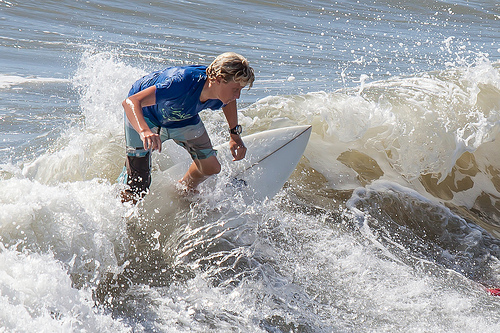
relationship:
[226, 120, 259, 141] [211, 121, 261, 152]
watch on wrist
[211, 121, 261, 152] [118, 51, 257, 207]
wrist of man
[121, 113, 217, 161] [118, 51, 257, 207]
shortsa of man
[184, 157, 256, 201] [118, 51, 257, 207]
knee of man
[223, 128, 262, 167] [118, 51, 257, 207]
hand or man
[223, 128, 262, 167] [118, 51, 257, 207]
hand of man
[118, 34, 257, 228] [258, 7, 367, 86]
man in water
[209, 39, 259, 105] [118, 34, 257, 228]
head of man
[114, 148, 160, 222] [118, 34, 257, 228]
leg of man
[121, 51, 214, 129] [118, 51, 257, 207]
shirt on man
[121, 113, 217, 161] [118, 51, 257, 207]
shortsa on man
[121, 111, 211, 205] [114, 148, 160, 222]
shorts has leg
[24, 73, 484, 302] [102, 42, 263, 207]
waves around surfer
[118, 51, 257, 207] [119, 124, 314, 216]
man on surfboard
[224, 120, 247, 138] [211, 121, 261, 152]
watch on wrist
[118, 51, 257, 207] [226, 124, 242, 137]
man has watch